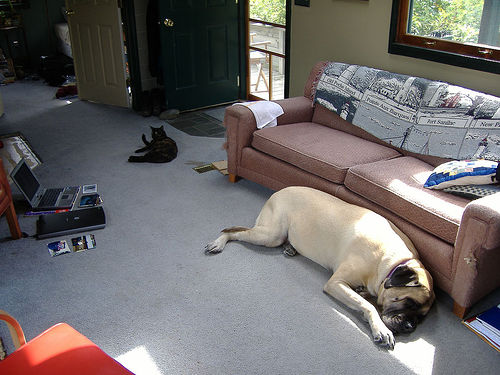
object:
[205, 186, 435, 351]
dog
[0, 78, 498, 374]
carpet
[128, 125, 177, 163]
cat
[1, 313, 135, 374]
chair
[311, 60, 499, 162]
throw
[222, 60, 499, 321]
couch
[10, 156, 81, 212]
laptop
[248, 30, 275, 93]
chair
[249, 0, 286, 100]
balcony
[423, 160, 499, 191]
pillow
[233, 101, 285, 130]
towel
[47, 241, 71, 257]
photo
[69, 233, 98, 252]
photo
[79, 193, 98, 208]
cd case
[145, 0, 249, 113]
door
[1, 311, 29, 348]
arm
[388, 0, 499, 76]
window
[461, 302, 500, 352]
books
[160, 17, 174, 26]
knob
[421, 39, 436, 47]
handle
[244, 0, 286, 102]
screen door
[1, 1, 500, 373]
room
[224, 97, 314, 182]
arm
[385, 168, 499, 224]
sunlight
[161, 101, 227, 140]
tile